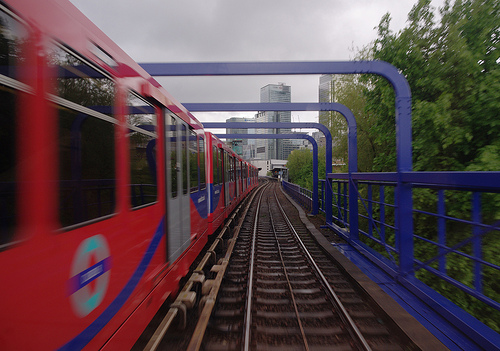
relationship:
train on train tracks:
[1, 2, 261, 348] [1, 0, 499, 335]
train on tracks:
[1, 2, 262, 345] [195, 125, 373, 349]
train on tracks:
[1, 2, 262, 345] [234, 169, 383, 349]